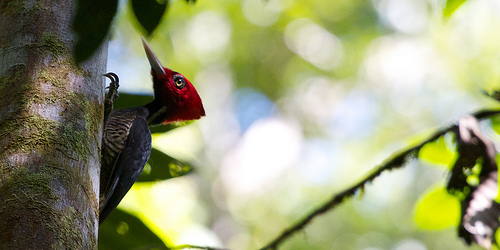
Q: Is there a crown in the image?
A: No, there are no crowns.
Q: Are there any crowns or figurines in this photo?
A: No, there are no crowns or figurines.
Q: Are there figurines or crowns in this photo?
A: No, there are no crowns or figurines.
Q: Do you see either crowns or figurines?
A: No, there are no crowns or figurines.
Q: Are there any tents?
A: No, there are no tents.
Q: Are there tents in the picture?
A: No, there are no tents.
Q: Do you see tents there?
A: No, there are no tents.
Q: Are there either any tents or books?
A: No, there are no tents or books.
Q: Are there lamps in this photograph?
A: No, there are no lamps.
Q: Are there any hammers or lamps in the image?
A: No, there are no lamps or hammers.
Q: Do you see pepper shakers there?
A: No, there are no pepper shakers.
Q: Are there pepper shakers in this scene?
A: No, there are no pepper shakers.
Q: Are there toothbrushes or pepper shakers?
A: No, there are no pepper shakers or toothbrushes.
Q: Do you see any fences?
A: No, there are no fences.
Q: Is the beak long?
A: Yes, the beak is long.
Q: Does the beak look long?
A: Yes, the beak is long.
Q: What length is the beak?
A: The beak is long.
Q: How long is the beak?
A: The beak is long.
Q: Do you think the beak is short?
A: No, the beak is long.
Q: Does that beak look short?
A: No, the beak is long.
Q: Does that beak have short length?
A: No, the beak is long.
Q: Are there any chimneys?
A: No, there are no chimneys.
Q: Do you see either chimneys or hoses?
A: No, there are no chimneys or hoses.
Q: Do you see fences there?
A: No, there are no fences.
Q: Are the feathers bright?
A: Yes, the feathers are bright.